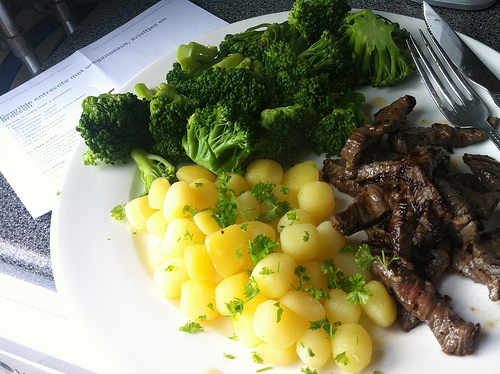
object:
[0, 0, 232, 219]
paper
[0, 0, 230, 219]
recipe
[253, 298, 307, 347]
potato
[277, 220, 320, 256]
potato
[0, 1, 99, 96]
floor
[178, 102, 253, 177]
piece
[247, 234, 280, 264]
herb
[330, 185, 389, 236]
steak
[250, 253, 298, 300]
boiled potatoes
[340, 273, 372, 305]
parsley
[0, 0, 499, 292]
countertop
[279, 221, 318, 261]
food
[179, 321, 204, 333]
leaf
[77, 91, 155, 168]
plant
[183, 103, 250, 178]
broccoli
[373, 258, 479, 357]
meat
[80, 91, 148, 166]
dish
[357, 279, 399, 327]
oregano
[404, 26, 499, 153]
fork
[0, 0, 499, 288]
counter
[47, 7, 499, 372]
plate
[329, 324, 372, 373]
pasta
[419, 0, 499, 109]
knife